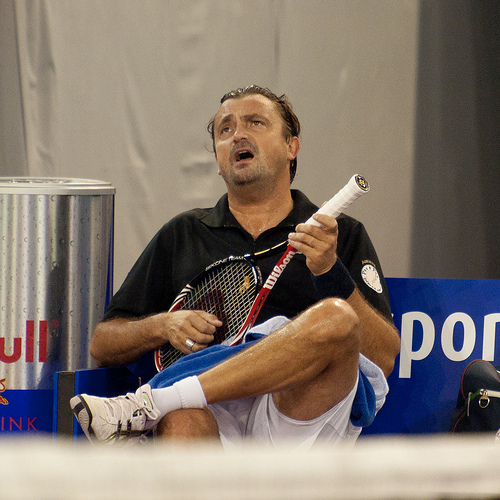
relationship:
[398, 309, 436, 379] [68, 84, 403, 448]
letter p beside guy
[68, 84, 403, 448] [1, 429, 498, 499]
guy on bench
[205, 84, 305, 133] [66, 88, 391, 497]
hair on man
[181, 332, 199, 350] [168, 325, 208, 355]
ring on finger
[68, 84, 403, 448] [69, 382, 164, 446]
guy wearing white sneakers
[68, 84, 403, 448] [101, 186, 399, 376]
guy wearing shirt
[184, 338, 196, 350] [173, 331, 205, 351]
ring on finger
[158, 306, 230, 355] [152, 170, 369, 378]
hand strumming racket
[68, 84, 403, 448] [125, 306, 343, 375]
guy has crossed legs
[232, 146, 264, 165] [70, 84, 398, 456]
mouth of guy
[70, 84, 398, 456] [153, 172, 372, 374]
guy strumming racket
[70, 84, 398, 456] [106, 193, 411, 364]
guy in shirt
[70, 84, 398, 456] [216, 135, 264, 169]
guy with mouth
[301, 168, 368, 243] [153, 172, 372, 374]
white handle of racket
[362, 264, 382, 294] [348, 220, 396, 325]
circle on sleeve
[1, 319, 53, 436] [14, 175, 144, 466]
logo on advertisement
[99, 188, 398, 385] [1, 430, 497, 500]
shirt of net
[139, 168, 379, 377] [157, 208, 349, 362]
racket in hands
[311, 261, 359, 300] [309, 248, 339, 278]
sweatband on wrist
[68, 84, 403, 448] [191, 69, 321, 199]
guy has hair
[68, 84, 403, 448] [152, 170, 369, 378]
guy holding racket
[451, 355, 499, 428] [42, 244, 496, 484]
bag on a bench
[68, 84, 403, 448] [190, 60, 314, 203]
guy has head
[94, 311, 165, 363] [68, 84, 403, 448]
arm of guy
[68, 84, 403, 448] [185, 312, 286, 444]
guy sitting chair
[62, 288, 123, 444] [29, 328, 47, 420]
ink on part